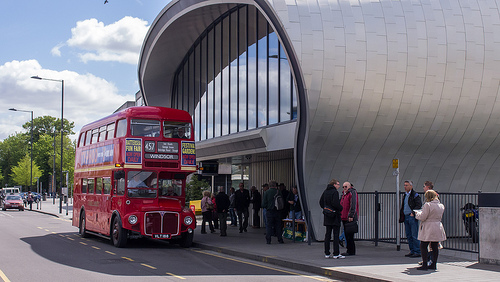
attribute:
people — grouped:
[180, 177, 310, 237]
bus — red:
[52, 74, 225, 257]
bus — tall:
[51, 109, 215, 239]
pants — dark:
[238, 206, 248, 226]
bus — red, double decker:
[55, 83, 206, 248]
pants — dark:
[402, 212, 423, 252]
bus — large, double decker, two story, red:
[68, 101, 200, 249]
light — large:
[32, 70, 72, 212]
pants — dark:
[317, 214, 344, 266]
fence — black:
[349, 185, 499, 250]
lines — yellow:
[86, 230, 136, 279]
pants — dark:
[248, 201, 265, 228]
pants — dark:
[200, 208, 214, 230]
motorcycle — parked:
[460, 198, 480, 243]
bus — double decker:
[36, 109, 233, 240]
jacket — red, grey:
[329, 169, 364, 254]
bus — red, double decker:
[64, 103, 204, 258]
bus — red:
[57, 71, 207, 266]